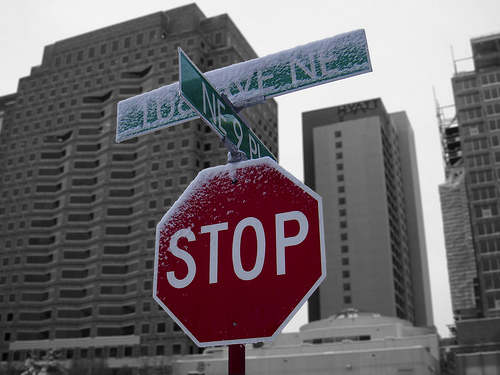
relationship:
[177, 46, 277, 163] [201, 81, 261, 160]
street sign has text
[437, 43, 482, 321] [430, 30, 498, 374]
repair on building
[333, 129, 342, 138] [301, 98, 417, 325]
window on building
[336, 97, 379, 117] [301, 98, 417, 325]
word on building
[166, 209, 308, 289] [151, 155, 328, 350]
word on stop sign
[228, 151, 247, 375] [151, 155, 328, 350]
pole holding stop sign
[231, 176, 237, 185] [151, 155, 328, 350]
nail on stop sign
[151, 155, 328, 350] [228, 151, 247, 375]
stop sign on pole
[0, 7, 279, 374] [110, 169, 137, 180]
building has window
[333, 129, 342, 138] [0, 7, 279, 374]
window on building